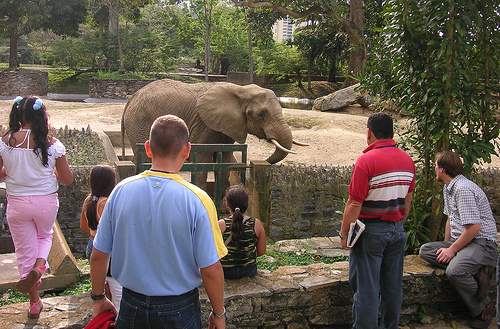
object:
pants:
[5, 192, 59, 286]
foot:
[14, 260, 43, 317]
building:
[272, 18, 318, 43]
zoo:
[0, 0, 500, 329]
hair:
[222, 185, 249, 242]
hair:
[84, 165, 115, 231]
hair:
[2, 97, 51, 168]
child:
[217, 185, 265, 280]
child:
[79, 165, 120, 277]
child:
[0, 95, 73, 318]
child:
[89, 114, 225, 329]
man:
[338, 113, 416, 329]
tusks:
[293, 139, 310, 146]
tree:
[408, 0, 498, 151]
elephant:
[121, 79, 311, 214]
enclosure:
[1, 62, 500, 241]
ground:
[308, 115, 358, 163]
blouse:
[0, 129, 67, 197]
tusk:
[271, 139, 298, 154]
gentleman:
[419, 151, 499, 329]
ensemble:
[418, 237, 498, 318]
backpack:
[84, 310, 118, 328]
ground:
[208, 72, 229, 82]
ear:
[195, 81, 247, 144]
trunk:
[266, 119, 293, 164]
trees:
[0, 0, 89, 87]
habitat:
[0, 60, 500, 237]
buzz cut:
[149, 115, 190, 161]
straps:
[82, 310, 116, 329]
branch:
[192, 3, 212, 31]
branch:
[340, 4, 367, 88]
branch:
[13, 5, 40, 18]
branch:
[385, 1, 442, 29]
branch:
[118, 1, 146, 27]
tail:
[121, 92, 136, 161]